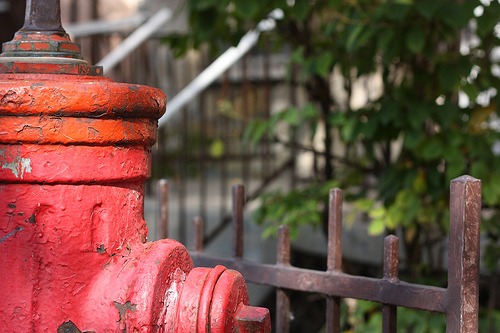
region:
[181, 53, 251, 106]
a white rail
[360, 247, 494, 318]
a brown fence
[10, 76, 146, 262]
a red fire hydrant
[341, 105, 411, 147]
green leaves on the tree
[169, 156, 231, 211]
stairs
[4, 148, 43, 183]
scratches on the fire hydrant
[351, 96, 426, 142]
the leaves on the tree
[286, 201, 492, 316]
the fence is next to the fire hydrant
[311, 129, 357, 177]
a tree branch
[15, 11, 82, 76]
top of the fire hydrant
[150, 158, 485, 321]
iron gate along way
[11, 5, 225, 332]
red fire hydrant standing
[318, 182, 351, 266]
spike of iron gate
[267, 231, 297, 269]
spike of iron gate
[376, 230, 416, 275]
spike of iron gate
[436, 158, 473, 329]
spike of iron gate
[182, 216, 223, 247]
spike of iron gate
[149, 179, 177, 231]
spike of iron gate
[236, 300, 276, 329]
bolt on fire hydrant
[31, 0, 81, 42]
bolt on fire hydrant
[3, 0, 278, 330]
red fire hydrant with orange top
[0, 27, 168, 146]
orange top on fire hydrant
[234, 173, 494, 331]
iron fence near fire hydrant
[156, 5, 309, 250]
metal railing on stairs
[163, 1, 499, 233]
green tree beside building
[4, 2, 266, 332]
old fire hydrant with chipped paint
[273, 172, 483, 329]
old metal fence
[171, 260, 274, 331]
cap on water outlet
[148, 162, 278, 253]
steps into building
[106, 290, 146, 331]
chipped paint on fire hydrant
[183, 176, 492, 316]
an iron fence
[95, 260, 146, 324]
cracked red paint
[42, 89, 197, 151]
old orange paint on a fire hydrant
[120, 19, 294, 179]
railing for stairs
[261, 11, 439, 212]
green tree leaves next to a fence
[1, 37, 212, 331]
orange and red fire hydrant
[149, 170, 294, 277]
concrete stairs on the ground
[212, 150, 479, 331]
a jagged metal fence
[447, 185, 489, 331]
rusted metal gate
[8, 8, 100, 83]
silver spot with no paint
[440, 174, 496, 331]
This is a metal bar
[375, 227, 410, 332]
This is a metal bar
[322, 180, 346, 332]
This is a metal bar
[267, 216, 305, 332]
This is a metal bar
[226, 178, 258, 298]
This is a metal bar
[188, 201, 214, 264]
This is a metal bar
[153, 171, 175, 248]
This is a metal bar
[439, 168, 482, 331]
This is a rusty metal bar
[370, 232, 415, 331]
This is a rusty metal bar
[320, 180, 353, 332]
This is a rusty metal bar